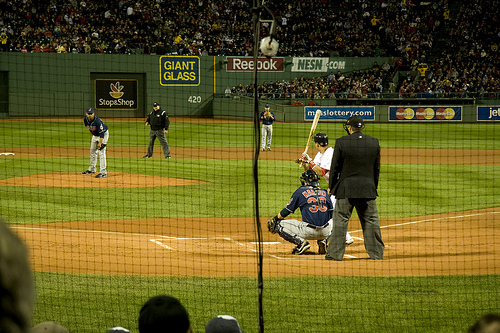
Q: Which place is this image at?
A: It is at the field.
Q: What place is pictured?
A: It is a field.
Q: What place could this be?
A: It is a field.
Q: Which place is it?
A: It is a field.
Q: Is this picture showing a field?
A: Yes, it is showing a field.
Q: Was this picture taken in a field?
A: Yes, it was taken in a field.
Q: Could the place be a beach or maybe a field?
A: It is a field.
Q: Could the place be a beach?
A: No, it is a field.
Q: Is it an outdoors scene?
A: Yes, it is outdoors.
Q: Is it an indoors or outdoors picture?
A: It is outdoors.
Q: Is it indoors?
A: No, it is outdoors.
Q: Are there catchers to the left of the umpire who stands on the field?
A: Yes, there is a catcher to the left of the umpire.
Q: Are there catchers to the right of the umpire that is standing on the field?
A: No, the catcher is to the left of the umpire.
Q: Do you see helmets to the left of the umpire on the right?
A: No, there is a catcher to the left of the umpire.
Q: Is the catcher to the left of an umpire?
A: Yes, the catcher is to the left of an umpire.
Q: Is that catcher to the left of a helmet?
A: No, the catcher is to the left of an umpire.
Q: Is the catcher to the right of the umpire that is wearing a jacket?
A: No, the catcher is to the left of the umpire.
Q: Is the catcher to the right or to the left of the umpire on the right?
A: The catcher is to the left of the umpire.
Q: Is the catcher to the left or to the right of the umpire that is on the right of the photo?
A: The catcher is to the left of the umpire.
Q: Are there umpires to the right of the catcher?
A: Yes, there is an umpire to the right of the catcher.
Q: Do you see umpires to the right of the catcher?
A: Yes, there is an umpire to the right of the catcher.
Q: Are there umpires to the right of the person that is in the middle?
A: Yes, there is an umpire to the right of the catcher.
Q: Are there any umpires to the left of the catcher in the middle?
A: No, the umpire is to the right of the catcher.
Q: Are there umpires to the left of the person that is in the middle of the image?
A: No, the umpire is to the right of the catcher.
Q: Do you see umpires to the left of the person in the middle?
A: No, the umpire is to the right of the catcher.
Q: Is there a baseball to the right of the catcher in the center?
A: No, there is an umpire to the right of the catcher.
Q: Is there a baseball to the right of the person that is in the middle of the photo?
A: No, there is an umpire to the right of the catcher.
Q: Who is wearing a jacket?
A: The umpire is wearing a jacket.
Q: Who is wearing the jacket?
A: The umpire is wearing a jacket.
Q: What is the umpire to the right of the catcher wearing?
A: The umpire is wearing a jacket.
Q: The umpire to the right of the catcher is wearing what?
A: The umpire is wearing a jacket.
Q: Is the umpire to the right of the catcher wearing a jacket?
A: Yes, the umpire is wearing a jacket.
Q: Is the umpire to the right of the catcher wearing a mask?
A: No, the umpire is wearing a jacket.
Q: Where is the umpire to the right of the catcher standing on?
A: The umpire is standing on the field.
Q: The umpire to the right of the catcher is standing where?
A: The umpire is standing on the field.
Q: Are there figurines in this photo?
A: No, there are no figurines.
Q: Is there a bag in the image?
A: No, there are no bags.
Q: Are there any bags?
A: No, there are no bags.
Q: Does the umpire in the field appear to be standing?
A: Yes, the umpire is standing.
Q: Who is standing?
A: The umpire is standing.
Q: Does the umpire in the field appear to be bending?
A: No, the umpire is standing.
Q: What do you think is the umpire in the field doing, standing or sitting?
A: The umpire is standing.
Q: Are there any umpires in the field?
A: Yes, there is an umpire in the field.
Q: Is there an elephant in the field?
A: No, there is an umpire in the field.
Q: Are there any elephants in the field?
A: No, there is an umpire in the field.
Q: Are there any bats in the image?
A: Yes, there is a bat.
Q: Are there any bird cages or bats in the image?
A: Yes, there is a bat.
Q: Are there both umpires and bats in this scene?
A: Yes, there are both a bat and an umpire.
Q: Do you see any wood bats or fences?
A: Yes, there is a wood bat.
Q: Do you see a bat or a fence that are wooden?
A: Yes, the bat is wooden.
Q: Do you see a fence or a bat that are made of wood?
A: Yes, the bat is made of wood.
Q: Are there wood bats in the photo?
A: Yes, there is a wood bat.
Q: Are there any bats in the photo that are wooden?
A: Yes, there is a bat that is wooden.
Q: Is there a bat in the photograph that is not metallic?
A: Yes, there is a wooden bat.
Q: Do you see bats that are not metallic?
A: Yes, there is a wooden bat.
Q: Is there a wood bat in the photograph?
A: Yes, there is a bat that is made of wood.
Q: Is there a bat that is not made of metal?
A: Yes, there is a bat that is made of wood.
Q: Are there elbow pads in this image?
A: No, there are no elbow pads.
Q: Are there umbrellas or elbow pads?
A: No, there are no elbow pads or umbrellas.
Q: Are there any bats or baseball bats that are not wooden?
A: No, there is a bat but it is wooden.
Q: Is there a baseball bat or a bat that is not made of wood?
A: No, there is a bat but it is made of wood.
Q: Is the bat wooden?
A: Yes, the bat is wooden.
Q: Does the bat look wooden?
A: Yes, the bat is wooden.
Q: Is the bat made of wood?
A: Yes, the bat is made of wood.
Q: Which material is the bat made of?
A: The bat is made of wood.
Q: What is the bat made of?
A: The bat is made of wood.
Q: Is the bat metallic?
A: No, the bat is wooden.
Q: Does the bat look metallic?
A: No, the bat is wooden.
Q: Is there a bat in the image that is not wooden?
A: No, there is a bat but it is wooden.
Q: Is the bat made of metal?
A: No, the bat is made of wood.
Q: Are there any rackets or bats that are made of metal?
A: No, there is a bat but it is made of wood.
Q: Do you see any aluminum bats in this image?
A: No, there is a bat but it is made of wood.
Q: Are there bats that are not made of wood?
A: No, there is a bat but it is made of wood.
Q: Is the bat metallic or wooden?
A: The bat is wooden.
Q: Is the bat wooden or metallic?
A: The bat is wooden.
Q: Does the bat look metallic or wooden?
A: The bat is wooden.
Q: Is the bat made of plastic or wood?
A: The bat is made of wood.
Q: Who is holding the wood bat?
A: The batter is holding the bat.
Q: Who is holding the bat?
A: The batter is holding the bat.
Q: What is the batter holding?
A: The batter is holding the bat.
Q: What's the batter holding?
A: The batter is holding the bat.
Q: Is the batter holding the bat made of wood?
A: Yes, the batter is holding the bat.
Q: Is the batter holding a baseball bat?
A: No, the batter is holding the bat.